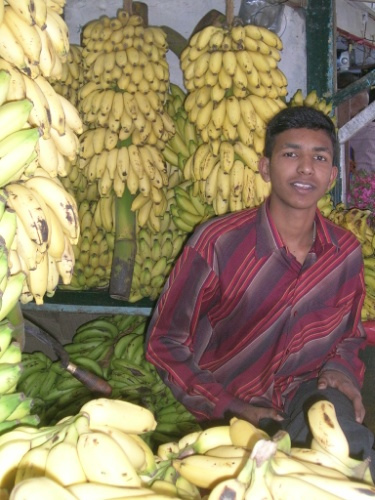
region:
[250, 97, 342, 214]
Black hair on a guy's head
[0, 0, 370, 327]
Many hanging yellow bananas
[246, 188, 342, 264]
A collar of a shirt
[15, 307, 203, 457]
The bananas are green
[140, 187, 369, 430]
A red and black long sleeved shirt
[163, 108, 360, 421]
boy is wearing a shirt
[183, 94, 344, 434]
boy is wearing a shirt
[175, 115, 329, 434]
boy is wearing a shirt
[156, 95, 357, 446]
boy is wearing a shirt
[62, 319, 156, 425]
the bananas are green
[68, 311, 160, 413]
the bananas are green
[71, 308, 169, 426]
the bananas are green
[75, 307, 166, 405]
the bananas are green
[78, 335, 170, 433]
the bananas are green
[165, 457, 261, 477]
a ripe banana on sale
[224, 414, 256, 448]
a ripe banana on sale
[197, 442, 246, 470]
a ripe banana on sale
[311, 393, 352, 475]
a ripe banana on sale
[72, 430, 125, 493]
a ripe banana on sale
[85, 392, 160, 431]
a ripe banana on sale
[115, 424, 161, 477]
a ripe banana on sale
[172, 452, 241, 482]
a ripe banana on sale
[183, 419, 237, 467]
a ripe banana on sale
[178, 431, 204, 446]
a ripe banana on sale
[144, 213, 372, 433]
man wearing maroon striped shirt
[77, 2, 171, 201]
large bunch of yellow bananas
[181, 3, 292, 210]
large bunch of yellow bananas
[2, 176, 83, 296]
large bunch of yellow bananas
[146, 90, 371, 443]
dark skinned man selling fruit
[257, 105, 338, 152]
man with short dark hair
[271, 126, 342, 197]
smiling face of dark skinned man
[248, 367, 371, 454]
man holding black cloth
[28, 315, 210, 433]
green bananas in background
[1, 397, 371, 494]
yellow bananas in foreground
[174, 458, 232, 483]
a ripe banana on sale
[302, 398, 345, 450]
a ripe banana on sale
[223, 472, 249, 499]
a ripe banana on sale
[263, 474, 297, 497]
a ripe banana on sale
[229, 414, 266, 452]
a ripe banana on sale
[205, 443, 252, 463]
a ripe banana on sale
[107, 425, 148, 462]
a ripe banana on sale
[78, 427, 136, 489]
a ripe banana on sale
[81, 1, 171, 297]
a tall beam of bananas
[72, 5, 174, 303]
bananas sitting on a pole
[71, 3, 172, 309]
a pole covered in bananas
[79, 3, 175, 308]
fruit bunches along a tree trunk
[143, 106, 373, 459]
the man is sitting down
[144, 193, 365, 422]
the shirt has stripes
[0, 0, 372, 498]
the bananas are yellow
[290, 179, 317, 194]
the mouth is slightly opened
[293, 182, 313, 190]
the teeth are white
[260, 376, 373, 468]
the pants are black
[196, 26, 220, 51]
the banana is green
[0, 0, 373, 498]
the bananas around the man